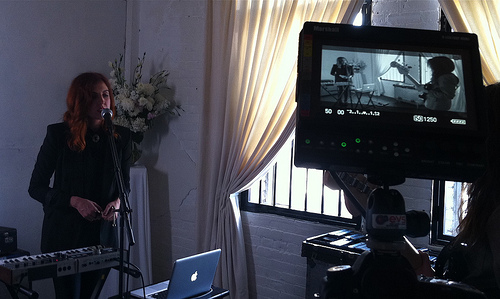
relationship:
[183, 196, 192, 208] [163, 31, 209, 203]
brick on wall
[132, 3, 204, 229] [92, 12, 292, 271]
brick on wall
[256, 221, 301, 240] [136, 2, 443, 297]
brick on wall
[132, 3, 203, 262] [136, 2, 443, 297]
brick on wall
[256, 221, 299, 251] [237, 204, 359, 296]
brick on wall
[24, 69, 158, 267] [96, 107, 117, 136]
woman singing into microphone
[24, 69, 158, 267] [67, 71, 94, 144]
woman with hair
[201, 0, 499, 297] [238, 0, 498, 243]
curtains on window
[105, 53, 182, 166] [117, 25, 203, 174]
bouquet in corner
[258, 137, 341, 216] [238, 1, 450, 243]
bars on window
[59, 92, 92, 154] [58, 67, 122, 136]
hair on head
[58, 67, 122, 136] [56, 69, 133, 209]
head of woman